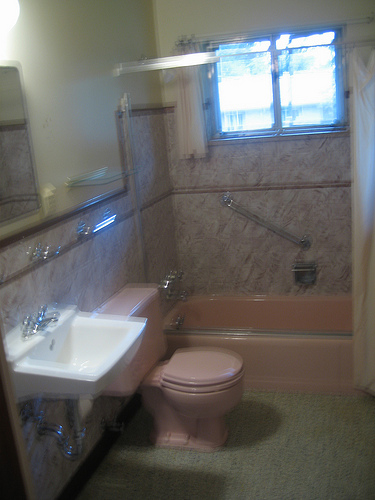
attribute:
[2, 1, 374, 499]
picture — blurry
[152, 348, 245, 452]
toilet bowl — salmon, pink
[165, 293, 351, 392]
bathtub — salmon, pink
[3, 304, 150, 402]
bathroom sink — white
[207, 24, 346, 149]
window — small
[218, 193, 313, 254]
handle bar — sideways, silver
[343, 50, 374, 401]
shower curtain — partially visible, white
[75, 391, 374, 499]
floor — dark green, light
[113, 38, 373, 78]
curtain holder — silver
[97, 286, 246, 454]
ceramic toilet — pink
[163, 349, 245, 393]
toilet seat — plastic, pink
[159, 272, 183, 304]
faucet — silver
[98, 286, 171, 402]
toilet tank — pink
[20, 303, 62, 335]
faucet — silver